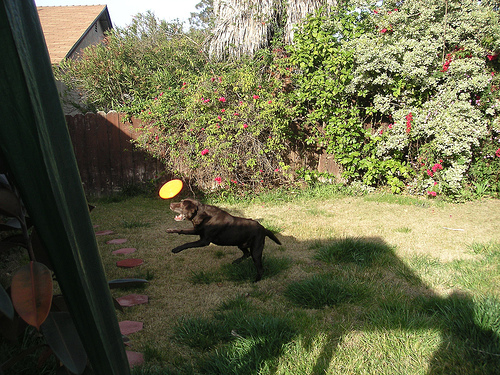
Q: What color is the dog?
A: Black.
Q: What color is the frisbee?
A: Yellow.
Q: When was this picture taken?
A: Daytime.